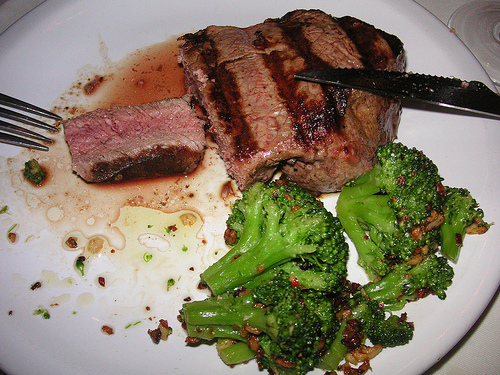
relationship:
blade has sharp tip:
[294, 67, 500, 121] [292, 68, 304, 81]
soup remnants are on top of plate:
[100, 37, 186, 108] [1, 2, 499, 373]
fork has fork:
[0, 91, 60, 150] [0, 93, 63, 151]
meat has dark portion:
[63, 96, 208, 182] [88, 146, 202, 180]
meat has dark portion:
[180, 8, 407, 193] [186, 30, 257, 166]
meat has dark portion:
[180, 8, 407, 193] [254, 31, 319, 153]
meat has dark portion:
[180, 8, 407, 193] [278, 19, 345, 135]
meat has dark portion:
[180, 8, 407, 193] [338, 15, 386, 74]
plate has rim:
[1, 2, 499, 373] [389, 287, 498, 373]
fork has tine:
[0, 91, 60, 150] [1, 122, 53, 142]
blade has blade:
[294, 67, 500, 121] [299, 69, 463, 83]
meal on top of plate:
[63, 9, 489, 374] [1, 2, 499, 373]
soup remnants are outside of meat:
[100, 37, 186, 108] [180, 8, 407, 193]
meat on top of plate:
[63, 96, 208, 182] [1, 2, 499, 373]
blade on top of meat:
[294, 67, 500, 121] [180, 8, 407, 193]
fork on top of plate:
[0, 91, 60, 150] [1, 2, 499, 373]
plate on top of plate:
[1, 2, 499, 373] [0, 0, 500, 372]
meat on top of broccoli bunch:
[180, 8, 407, 193] [179, 142, 494, 374]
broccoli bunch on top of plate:
[184, 142, 490, 374] [1, 2, 499, 373]